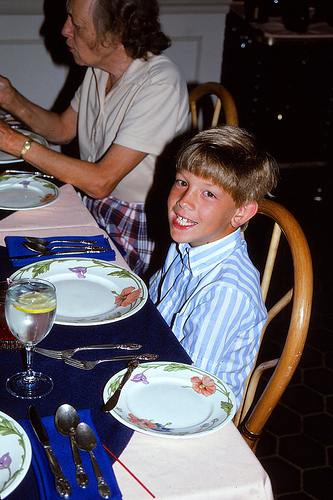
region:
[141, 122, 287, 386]
the boy is blond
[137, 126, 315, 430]
the boy sits on a wood chair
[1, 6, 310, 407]
the boy sits next an old woman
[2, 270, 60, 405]
a glass of water with a slice of lemon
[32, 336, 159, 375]
two forks color silver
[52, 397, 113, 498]
two spoons on a blue napkin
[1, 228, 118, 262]
utensils on a blue napkin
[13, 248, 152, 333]
an empty dish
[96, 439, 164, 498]
a red straw on a table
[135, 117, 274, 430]
boy wears a striped shirt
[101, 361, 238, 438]
a china plate with a flower pattern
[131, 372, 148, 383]
an image of a purple tulip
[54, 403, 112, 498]
two silver spoons on a napkin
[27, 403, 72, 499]
a silver knife on a blue napkin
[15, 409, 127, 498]
a blue folded napkin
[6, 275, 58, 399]
a water glass with a lemon wedge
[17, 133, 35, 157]
a gold bracelet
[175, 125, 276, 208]
blonde-brown hair on a boy's head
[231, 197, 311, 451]
a wooden chair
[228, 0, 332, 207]
a black stove in the background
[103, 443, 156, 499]
red stirrer stick on table cloth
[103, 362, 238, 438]
fine china with flower design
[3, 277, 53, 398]
clear glass with clear liquid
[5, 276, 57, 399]
glass with lemon in it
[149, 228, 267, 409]
shirt with white and blue stripes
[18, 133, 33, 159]
wearing gold watch on wrist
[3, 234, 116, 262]
silverwear undisturbed on blue napkin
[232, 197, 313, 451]
wooden back to chair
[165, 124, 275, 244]
smiling boy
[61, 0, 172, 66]
older woman with brown hair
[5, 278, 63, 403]
Water glass on table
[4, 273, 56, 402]
Water, ice and lemmon in glass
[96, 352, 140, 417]
Silver knife on plate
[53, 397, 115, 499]
Two spoons on a blue napkin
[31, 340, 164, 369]
Two forks on a table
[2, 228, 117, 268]
Silverware on a blue napkin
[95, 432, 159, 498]
Red straw on table cloth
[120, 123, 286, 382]
Boy sitting at table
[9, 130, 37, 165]
Gold watch on womans wrist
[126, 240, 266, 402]
Boy wearing blue and white shirt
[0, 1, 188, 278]
a woman wearing a white shirt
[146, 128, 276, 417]
a boy in a blue and white shirt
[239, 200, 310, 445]
a brown wooden dining chair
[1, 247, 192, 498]
a blue table runner on the table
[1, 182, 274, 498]
a white table cloth on table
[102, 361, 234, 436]
a white floral plate on the table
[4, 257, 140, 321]
a white floral plate on the table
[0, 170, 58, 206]
a white floral plate on the table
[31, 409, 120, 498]
a blue napkin on the table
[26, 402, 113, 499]
a knife and two spoons on blue napkin